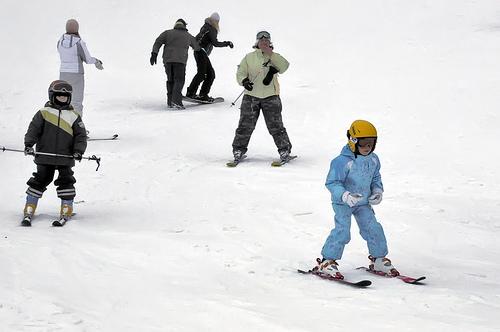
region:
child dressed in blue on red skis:
[295, 117, 425, 287]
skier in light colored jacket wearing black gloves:
[225, 30, 295, 165]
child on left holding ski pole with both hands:
[0, 80, 101, 225]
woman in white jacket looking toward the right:
[55, 15, 101, 132]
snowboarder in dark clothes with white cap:
[180, 10, 231, 100]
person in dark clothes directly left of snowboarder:
[147, 15, 202, 110]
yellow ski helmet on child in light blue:
[345, 117, 377, 152]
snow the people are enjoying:
[5, 0, 496, 326]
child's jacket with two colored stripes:
[25, 101, 85, 161]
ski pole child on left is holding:
[0, 143, 105, 159]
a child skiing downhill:
[297, 116, 427, 288]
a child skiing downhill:
[2, 81, 102, 228]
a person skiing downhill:
[224, 30, 299, 172]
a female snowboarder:
[184, 11, 235, 101]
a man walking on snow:
[146, 16, 208, 108]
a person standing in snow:
[57, 18, 104, 115]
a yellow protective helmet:
[345, 118, 377, 155]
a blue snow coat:
[325, 145, 385, 207]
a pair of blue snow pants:
[321, 201, 387, 257]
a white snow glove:
[341, 188, 361, 205]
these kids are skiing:
[4, 78, 441, 308]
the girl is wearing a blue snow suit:
[302, 105, 433, 303]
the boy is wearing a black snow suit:
[19, 69, 110, 246]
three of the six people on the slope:
[141, 3, 300, 176]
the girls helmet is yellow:
[332, 110, 391, 161]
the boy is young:
[13, 78, 114, 233]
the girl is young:
[303, 107, 427, 304]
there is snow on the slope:
[126, 207, 292, 318]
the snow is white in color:
[93, 199, 284, 317]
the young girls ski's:
[292, 259, 428, 291]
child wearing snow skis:
[309, 108, 461, 307]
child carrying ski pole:
[8, 67, 113, 240]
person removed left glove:
[228, 22, 307, 177]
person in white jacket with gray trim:
[34, 14, 122, 75]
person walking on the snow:
[134, 7, 205, 114]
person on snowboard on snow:
[187, 7, 230, 126]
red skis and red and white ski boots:
[290, 235, 446, 307]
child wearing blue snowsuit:
[326, 113, 403, 267]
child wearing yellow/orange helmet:
[328, 112, 398, 192]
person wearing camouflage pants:
[226, 28, 319, 191]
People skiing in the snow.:
[12, 11, 439, 317]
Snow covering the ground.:
[2, 7, 498, 330]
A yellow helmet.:
[348, 122, 379, 153]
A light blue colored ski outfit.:
[319, 147, 389, 258]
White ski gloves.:
[345, 191, 380, 206]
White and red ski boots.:
[315, 252, 395, 273]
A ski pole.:
[0, 137, 100, 162]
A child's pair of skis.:
[295, 250, 427, 290]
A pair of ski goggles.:
[55, 82, 72, 93]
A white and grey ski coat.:
[58, 34, 98, 71]